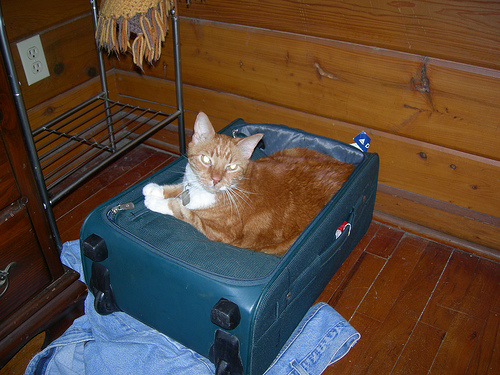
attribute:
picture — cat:
[3, 4, 494, 374]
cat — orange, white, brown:
[138, 113, 357, 247]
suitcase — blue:
[70, 116, 383, 366]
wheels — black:
[82, 291, 246, 374]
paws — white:
[139, 177, 173, 222]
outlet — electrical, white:
[14, 34, 51, 88]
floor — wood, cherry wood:
[363, 262, 491, 368]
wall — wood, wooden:
[391, 36, 487, 213]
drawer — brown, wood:
[0, 216, 48, 326]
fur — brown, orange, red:
[237, 157, 333, 240]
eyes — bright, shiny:
[197, 152, 238, 172]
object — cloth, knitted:
[90, 5, 190, 67]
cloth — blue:
[70, 315, 164, 369]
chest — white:
[183, 180, 215, 211]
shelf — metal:
[30, 90, 197, 186]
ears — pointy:
[189, 107, 263, 158]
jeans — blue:
[52, 320, 196, 373]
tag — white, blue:
[344, 131, 373, 154]